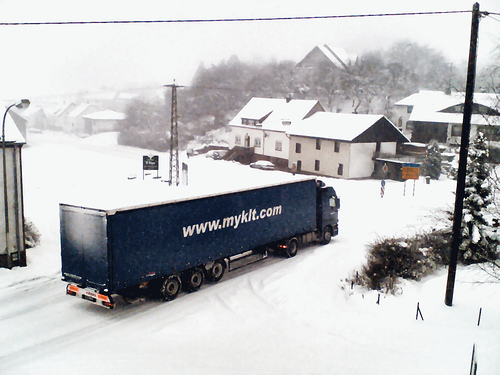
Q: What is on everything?
A: Snow.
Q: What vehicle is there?
A: Truck.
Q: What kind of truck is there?
A: 18-wheeler.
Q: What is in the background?
A: Houses.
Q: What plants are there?
A: Bushes.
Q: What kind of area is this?
A: Residential.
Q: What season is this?
A: Winter.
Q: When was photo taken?
A: In daytime.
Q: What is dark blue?
A: Truck.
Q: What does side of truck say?
A: Myklt.com.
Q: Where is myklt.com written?
A: Side of truck.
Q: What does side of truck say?
A: Myklt.com.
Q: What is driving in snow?
A: Large semi truck.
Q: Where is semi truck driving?
A: In the snow.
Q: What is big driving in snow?
A: Semi truck.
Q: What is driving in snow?
A: Huge semi truck.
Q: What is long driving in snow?
A: Semi truck.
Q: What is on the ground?
A: Snow.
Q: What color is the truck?
A: Blue.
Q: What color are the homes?
A: White.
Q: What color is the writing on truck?
A: White.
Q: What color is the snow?
A: White.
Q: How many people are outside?
A: None.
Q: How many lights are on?
A: None.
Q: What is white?
A: Snow.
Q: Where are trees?
A: In the distance.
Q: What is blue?
A: A truck.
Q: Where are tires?
A: Under the truck.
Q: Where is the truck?
A: On the road.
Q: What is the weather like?
A: Snowy.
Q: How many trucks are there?
A: One.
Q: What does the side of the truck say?
A: www.mykit.com.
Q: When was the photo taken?
A: Daytime.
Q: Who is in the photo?
A: Nobody.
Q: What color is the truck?
A: Blue.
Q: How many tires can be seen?
A: Five.